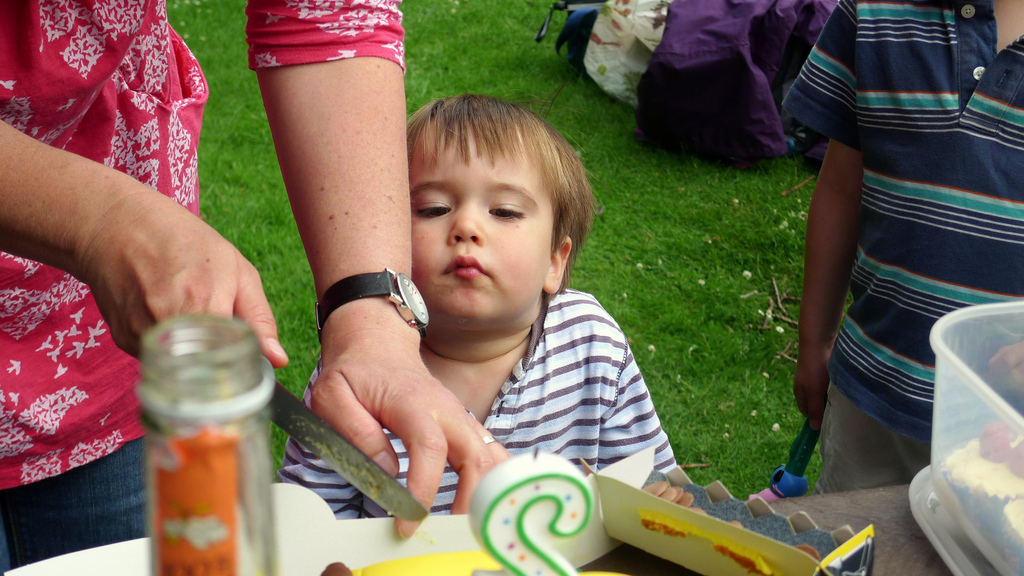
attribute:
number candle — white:
[469, 436, 606, 573]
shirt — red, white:
[5, 2, 398, 484]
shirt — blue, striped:
[778, 6, 1023, 379]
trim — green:
[473, 457, 609, 574]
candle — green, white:
[472, 452, 597, 573]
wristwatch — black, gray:
[307, 259, 432, 324]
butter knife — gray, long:
[264, 381, 427, 524]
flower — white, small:
[737, 265, 758, 284]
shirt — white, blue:
[277, 280, 690, 499]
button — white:
[501, 382, 524, 411]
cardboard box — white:
[595, 443, 875, 573]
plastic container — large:
[902, 307, 1007, 561]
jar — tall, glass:
[150, 315, 267, 573]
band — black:
[315, 275, 401, 313]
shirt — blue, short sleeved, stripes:
[778, 9, 1023, 431]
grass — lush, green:
[170, 3, 822, 484]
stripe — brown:
[533, 357, 629, 377]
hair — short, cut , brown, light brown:
[404, 94, 597, 263]